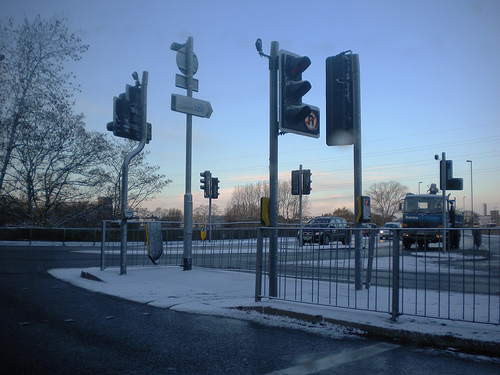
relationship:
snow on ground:
[46, 262, 499, 360] [2, 243, 500, 375]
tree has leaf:
[0, 12, 90, 191] [35, 15, 39, 19]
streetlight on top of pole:
[277, 52, 318, 138] [257, 37, 277, 305]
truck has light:
[401, 193, 463, 250] [402, 232, 410, 239]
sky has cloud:
[1, 3, 499, 218] [130, 171, 486, 215]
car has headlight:
[299, 216, 351, 248] [314, 231, 325, 235]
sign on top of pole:
[177, 47, 200, 76] [168, 37, 193, 271]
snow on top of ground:
[46, 262, 499, 360] [2, 243, 500, 375]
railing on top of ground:
[255, 226, 500, 332] [2, 243, 500, 375]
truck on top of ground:
[401, 193, 463, 250] [2, 243, 500, 375]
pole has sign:
[168, 37, 193, 271] [177, 47, 200, 76]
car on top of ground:
[299, 216, 351, 248] [2, 243, 500, 375]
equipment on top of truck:
[428, 183, 439, 196] [401, 193, 463, 250]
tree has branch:
[0, 12, 90, 191] [38, 34, 44, 60]